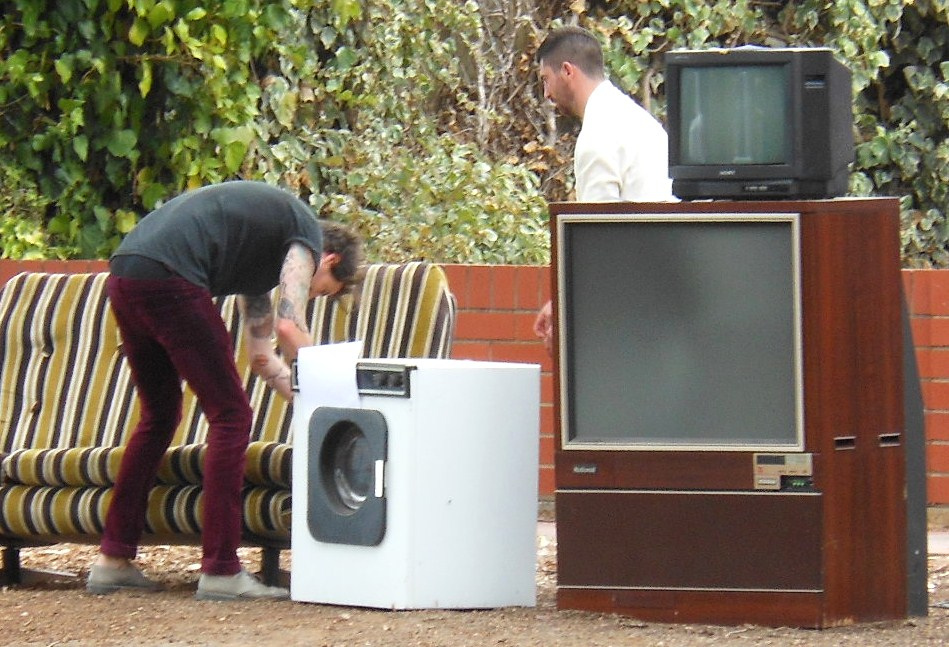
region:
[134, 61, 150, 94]
tree has a green leaf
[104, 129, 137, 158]
tree has a green leaf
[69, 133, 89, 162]
tree has a green leaf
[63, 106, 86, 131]
tree has a green leaf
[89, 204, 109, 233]
tree has a green leaf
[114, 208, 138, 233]
tree has a green leaf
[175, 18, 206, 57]
tree has a green leaf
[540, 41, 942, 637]
Two old televisions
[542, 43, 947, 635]
Small old TV on top of old TV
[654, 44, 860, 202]
Small old black TV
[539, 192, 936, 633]
Big old tv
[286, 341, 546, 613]
Old white washer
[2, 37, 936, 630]
Old sofa and appliances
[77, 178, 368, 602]
Guy wearing purple pants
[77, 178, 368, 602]
Guy has tattoos on his arms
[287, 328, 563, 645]
White washing machine on ground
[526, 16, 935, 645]
Small TV sitting on big TV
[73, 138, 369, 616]
Man wearing wine-colored pants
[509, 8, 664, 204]
Man wearing a white shirt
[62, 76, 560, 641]
Man looking at white washing machine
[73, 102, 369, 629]
Man wearing a gray shirt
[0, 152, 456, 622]
Man in front of striped couch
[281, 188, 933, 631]
White washing machine beside big TV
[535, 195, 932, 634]
Large, brown, floor-model TV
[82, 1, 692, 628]
Two men looking behind washing machine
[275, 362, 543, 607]
the washer is white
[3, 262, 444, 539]
the couch is striped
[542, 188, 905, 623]
the tv is large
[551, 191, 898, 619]
the tv is wood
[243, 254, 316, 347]
the man has tattoos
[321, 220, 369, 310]
the man has short hair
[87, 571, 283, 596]
the man has white shoes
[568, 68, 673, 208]
the man has a white shirt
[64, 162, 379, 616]
man is bend forward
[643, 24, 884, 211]
an old black TV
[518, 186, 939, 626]
an old TV is off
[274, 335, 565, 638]
a washing machine on the ground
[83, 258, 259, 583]
the pants are red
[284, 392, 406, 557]
the door of washing machine is gray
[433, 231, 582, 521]
a small wall color red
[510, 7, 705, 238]
man wearing white top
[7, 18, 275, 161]
the leaves are green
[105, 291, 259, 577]
the pants are red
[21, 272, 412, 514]
the couch is striped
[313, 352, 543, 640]
the machine is white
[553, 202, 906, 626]
the television is wooden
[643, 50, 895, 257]
the television is on top of large television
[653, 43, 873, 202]
the small tv is black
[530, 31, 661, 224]
the man is standing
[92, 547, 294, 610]
the shoes are gray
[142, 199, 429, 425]
the man is bent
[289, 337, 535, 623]
a small white dryer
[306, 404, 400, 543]
the door to a dryer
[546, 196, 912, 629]
an old style big screen tv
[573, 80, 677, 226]
a white dress shirt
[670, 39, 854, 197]
a small boxy tv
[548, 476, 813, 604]
speaker on a tv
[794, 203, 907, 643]
side of a tv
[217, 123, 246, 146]
A leaf on a stem.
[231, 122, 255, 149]
A leaf on a stem.